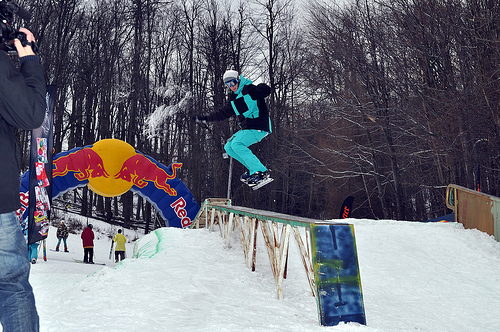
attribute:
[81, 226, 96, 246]
coat — red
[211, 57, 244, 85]
hat — white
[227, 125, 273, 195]
pants — light green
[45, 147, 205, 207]
balloon — promotional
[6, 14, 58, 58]
camera — in, held by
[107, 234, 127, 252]
coat — yellow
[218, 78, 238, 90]
glasses — ski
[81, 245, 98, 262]
pants — black 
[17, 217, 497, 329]
snow — white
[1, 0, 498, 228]
trees — bare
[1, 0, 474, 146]
sky — daytime sky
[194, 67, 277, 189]
person — clothed, airborn, snowboarding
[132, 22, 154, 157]
tree — brown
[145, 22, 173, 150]
tree — brown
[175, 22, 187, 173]
tree — brown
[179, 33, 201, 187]
tree — brown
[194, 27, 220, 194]
tree — brown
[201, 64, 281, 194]
suit — teal, black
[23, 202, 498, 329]
snow — white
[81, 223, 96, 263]
person — inthe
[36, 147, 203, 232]
banner — with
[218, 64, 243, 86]
cap — white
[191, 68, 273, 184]
person — wearing a blue and black jacket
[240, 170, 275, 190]
snowboard — white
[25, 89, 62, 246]
cloth banner — large, black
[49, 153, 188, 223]
logo — on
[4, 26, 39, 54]
hand — holds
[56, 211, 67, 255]
people — on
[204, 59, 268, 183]
people — on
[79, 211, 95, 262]
people — on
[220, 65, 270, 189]
person — on